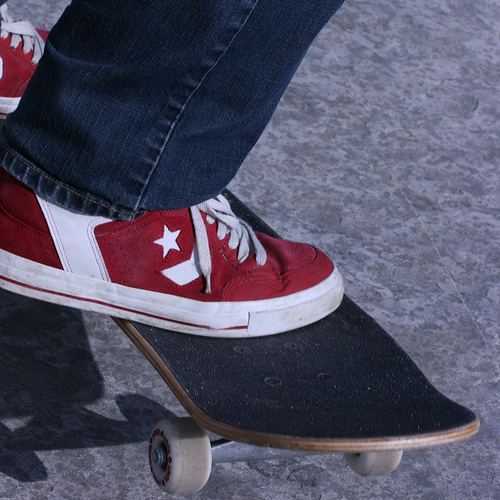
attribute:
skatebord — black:
[89, 170, 476, 483]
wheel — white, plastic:
[145, 413, 223, 498]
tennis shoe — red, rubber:
[2, 166, 344, 340]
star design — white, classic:
[152, 223, 187, 259]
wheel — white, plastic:
[349, 436, 410, 478]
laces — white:
[193, 187, 268, 301]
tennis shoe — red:
[1, 1, 60, 116]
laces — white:
[3, 3, 51, 67]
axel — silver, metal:
[210, 436, 359, 463]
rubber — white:
[3, 247, 342, 341]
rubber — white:
[3, 94, 29, 121]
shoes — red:
[3, 14, 346, 338]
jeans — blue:
[2, 0, 349, 218]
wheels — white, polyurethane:
[148, 420, 405, 495]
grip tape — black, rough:
[124, 186, 479, 440]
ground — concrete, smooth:
[7, 4, 497, 493]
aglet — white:
[202, 271, 214, 296]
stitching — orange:
[2, 136, 138, 221]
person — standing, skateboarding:
[1, 0, 352, 337]